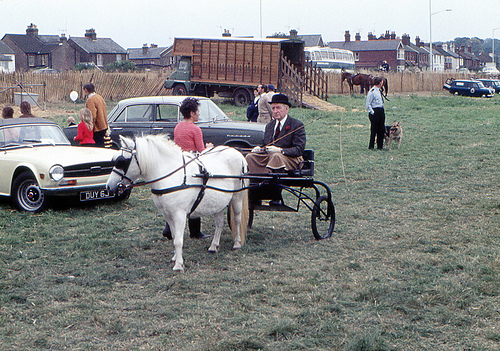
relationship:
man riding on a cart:
[245, 94, 305, 177] [244, 147, 333, 237]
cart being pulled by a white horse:
[244, 147, 333, 237] [98, 128, 253, 268]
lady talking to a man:
[159, 98, 207, 241] [254, 91, 306, 160]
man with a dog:
[346, 84, 391, 145] [378, 109, 428, 149]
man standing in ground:
[346, 84, 391, 145] [0, 102, 499, 349]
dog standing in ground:
[378, 109, 428, 149] [0, 102, 499, 349]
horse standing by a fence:
[362, 79, 385, 94] [325, 68, 498, 100]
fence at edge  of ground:
[0, 64, 498, 104] [0, 102, 499, 349]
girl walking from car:
[75, 109, 94, 144] [0, 116, 130, 212]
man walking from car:
[85, 78, 110, 145] [0, 116, 130, 212]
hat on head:
[266, 89, 294, 104] [266, 92, 293, 121]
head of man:
[266, 92, 293, 121] [246, 93, 307, 205]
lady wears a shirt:
[175, 98, 203, 151] [74, 121, 95, 144]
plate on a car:
[77, 187, 119, 203] [0, 116, 130, 212]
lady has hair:
[159, 98, 207, 241] [179, 98, 201, 117]